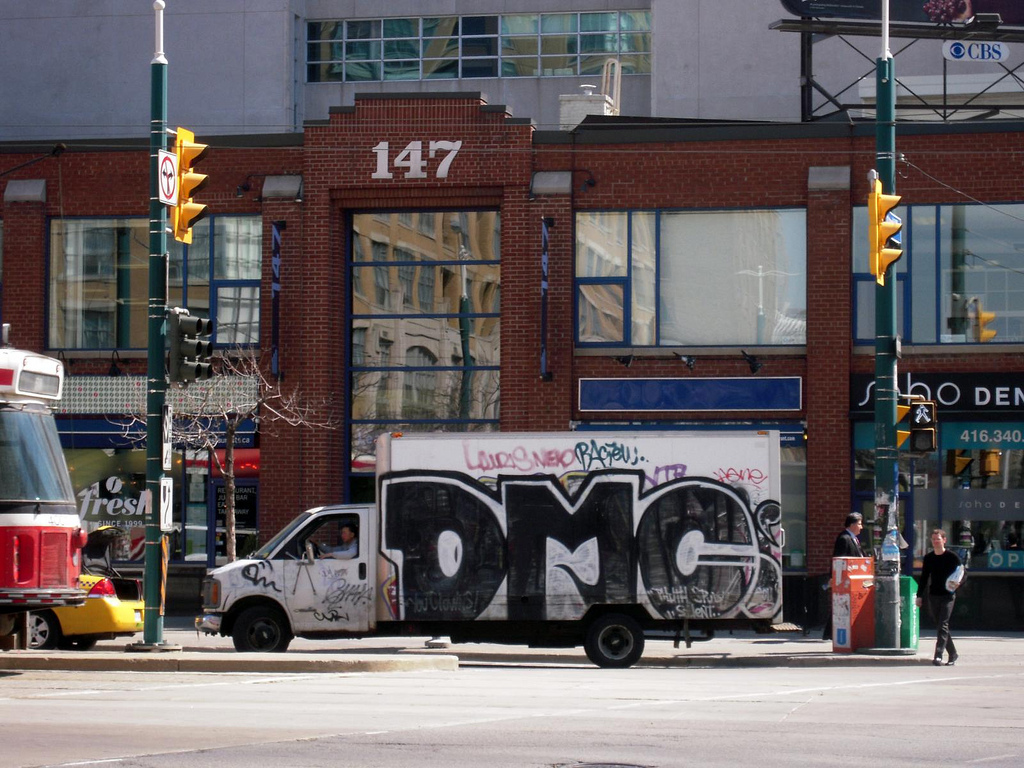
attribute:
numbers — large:
[359, 130, 474, 191]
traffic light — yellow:
[162, 115, 212, 252]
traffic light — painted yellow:
[863, 158, 907, 289]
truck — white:
[188, 421, 792, 659]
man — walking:
[911, 527, 976, 671]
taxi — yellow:
[11, 570, 142, 648]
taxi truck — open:
[12, 517, 147, 654]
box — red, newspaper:
[831, 549, 901, 649]